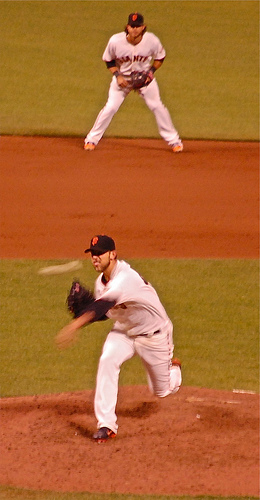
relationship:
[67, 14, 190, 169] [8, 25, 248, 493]
baseball player on field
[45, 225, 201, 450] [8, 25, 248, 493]
baseball player on field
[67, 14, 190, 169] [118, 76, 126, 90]
baseball player has hand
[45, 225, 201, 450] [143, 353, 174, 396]
baseball player has leg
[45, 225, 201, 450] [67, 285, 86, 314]
baseball player has glove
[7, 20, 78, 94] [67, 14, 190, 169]
grass behind baseball player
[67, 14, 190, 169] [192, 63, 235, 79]
baseball player in back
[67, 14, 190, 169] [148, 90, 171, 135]
baseball player has leg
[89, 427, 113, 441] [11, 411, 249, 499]
foot on mound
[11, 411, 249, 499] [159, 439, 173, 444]
mound of dirt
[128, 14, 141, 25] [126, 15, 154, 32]
hat on head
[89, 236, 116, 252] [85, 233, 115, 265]
hat on head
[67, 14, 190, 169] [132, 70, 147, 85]
baseball player has glove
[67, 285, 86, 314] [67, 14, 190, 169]
glove of baseball player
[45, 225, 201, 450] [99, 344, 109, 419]
baseball player lifting leg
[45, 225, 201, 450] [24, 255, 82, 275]
baseball player throwing ball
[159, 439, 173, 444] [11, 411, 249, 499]
dirt on mound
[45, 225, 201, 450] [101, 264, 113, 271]
baseball player has beard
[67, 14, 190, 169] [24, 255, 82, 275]
baseball player pitching ball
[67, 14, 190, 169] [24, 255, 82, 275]
baseball player preparing for ball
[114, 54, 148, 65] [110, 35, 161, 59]
word on jersey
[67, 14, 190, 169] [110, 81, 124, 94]
baseball player has pants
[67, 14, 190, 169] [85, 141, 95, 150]
baseball player wearing sneaker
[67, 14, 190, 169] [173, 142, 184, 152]
baseball player wearing sneaker